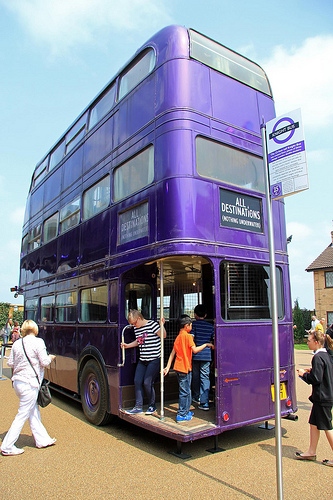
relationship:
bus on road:
[13, 20, 302, 461] [0, 338, 332, 498]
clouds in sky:
[0, 0, 332, 137] [3, 1, 322, 306]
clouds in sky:
[262, 33, 322, 126] [3, 1, 322, 306]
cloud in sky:
[6, 0, 175, 62] [3, 1, 322, 306]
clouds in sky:
[262, 33, 333, 129] [3, 1, 322, 306]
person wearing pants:
[118, 308, 167, 413] [131, 355, 163, 408]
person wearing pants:
[161, 313, 213, 423] [177, 365, 197, 430]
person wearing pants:
[189, 303, 216, 411] [189, 357, 213, 407]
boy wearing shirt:
[161, 313, 214, 423] [172, 329, 199, 375]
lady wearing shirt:
[0, 319, 56, 456] [11, 340, 49, 381]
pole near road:
[261, 127, 283, 499] [0, 338, 333, 500]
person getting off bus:
[118, 308, 167, 413] [33, 37, 297, 257]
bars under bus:
[167, 432, 227, 459] [13, 20, 302, 461]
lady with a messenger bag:
[0, 319, 56, 456] [34, 386, 57, 405]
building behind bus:
[304, 218, 333, 336] [13, 20, 302, 461]